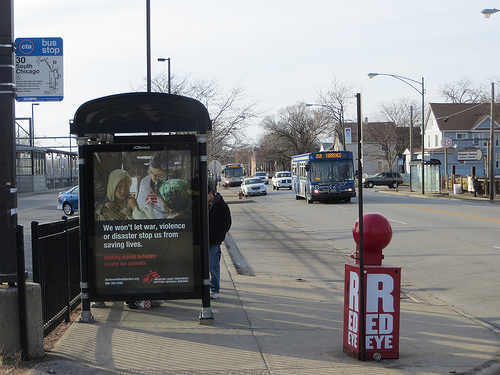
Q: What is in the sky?
A: Nothing.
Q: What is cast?
A: Shadow.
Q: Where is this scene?
A: At a bus stop.